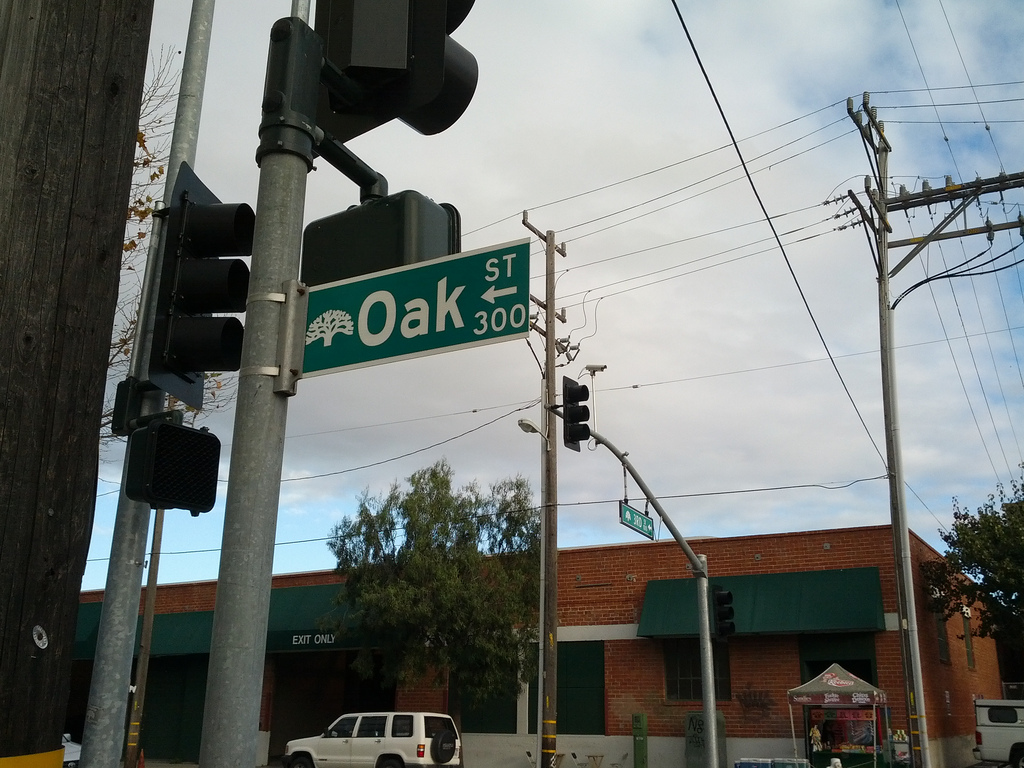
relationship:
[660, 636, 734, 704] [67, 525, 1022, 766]
window on building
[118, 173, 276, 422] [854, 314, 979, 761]
signal on pole